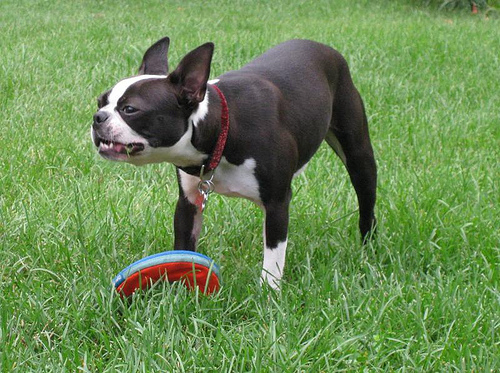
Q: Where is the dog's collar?
A: Around neck.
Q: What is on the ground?
A: Object.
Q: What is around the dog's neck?
A: Collar.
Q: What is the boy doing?
A: Playing.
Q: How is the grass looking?
A: Tall grass.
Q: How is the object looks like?
A: Good.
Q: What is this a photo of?
A: A dog playing with a rubber toy.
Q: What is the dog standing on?
A: Grass.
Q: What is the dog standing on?
A: Grass.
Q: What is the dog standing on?
A: Green grass.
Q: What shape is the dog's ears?
A: Long and pointy.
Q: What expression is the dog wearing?
A: Anger.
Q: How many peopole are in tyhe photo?
A: None.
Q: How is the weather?
A: Sunny.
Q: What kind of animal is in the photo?
A: A dog.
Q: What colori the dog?
A: Black and white.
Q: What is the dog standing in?
A: Grass.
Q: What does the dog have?
A: A toy.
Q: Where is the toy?
A: At the dog"s feet.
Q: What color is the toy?
A: Red and blue.